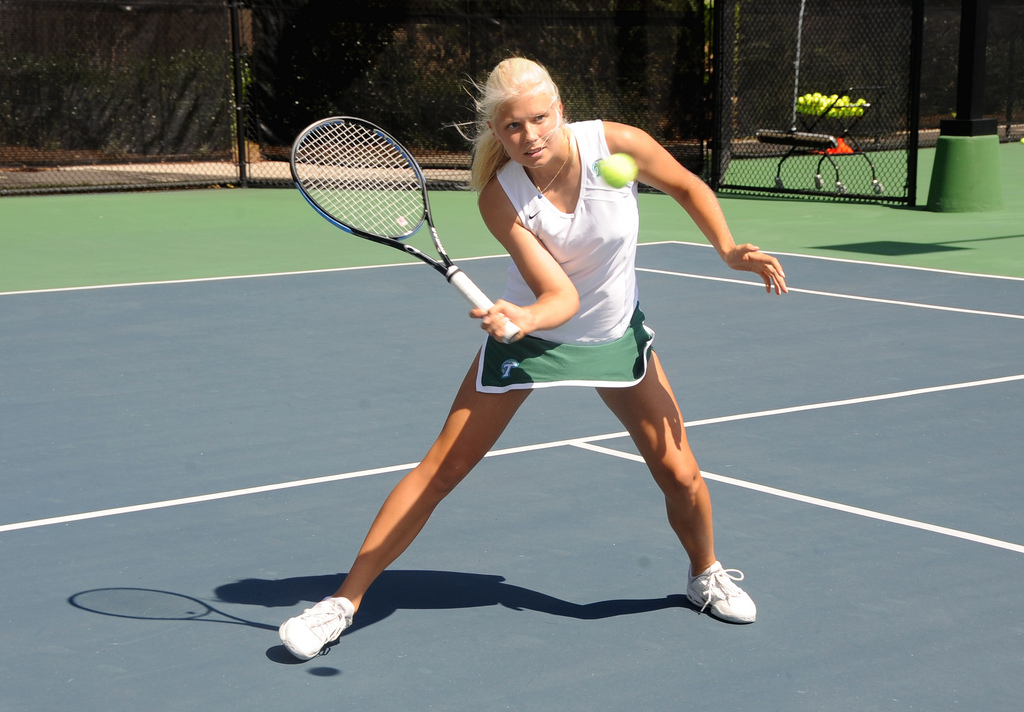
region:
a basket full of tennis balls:
[762, 45, 899, 204]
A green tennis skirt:
[378, 277, 742, 442]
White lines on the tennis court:
[762, 357, 986, 585]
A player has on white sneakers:
[236, 476, 795, 678]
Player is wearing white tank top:
[456, 88, 719, 366]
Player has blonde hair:
[450, 39, 631, 230]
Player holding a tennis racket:
[216, 88, 717, 380]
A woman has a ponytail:
[438, 47, 646, 255]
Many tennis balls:
[764, 37, 898, 202]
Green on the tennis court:
[48, 195, 186, 263]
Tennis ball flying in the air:
[574, 152, 655, 213]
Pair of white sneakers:
[256, 523, 819, 689]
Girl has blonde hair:
[427, 52, 625, 221]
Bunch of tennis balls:
[743, 44, 912, 248]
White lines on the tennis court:
[643, 262, 1021, 638]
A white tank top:
[438, 65, 681, 402]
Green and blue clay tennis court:
[66, 200, 881, 656]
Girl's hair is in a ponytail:
[403, 40, 613, 242]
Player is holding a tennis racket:
[257, 99, 705, 428]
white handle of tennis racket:
[461, 277, 494, 313]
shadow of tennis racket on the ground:
[62, 582, 234, 660]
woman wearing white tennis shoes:
[683, 558, 760, 626]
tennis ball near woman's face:
[520, 114, 658, 203]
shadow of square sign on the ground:
[806, 220, 1022, 263]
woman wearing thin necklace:
[524, 157, 573, 203]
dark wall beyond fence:
[9, 7, 231, 151]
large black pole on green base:
[934, 42, 999, 219]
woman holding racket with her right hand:
[477, 283, 542, 342]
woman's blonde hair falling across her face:
[533, 111, 573, 149]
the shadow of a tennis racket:
[53, 525, 269, 659]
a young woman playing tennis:
[204, 21, 811, 674]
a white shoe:
[672, 554, 770, 628]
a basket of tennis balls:
[742, 68, 907, 204]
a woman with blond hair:
[454, 49, 584, 204]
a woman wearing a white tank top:
[448, 55, 652, 344]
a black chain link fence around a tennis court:
[2, 19, 247, 198]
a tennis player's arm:
[435, 172, 587, 349]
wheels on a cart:
[758, 160, 902, 200]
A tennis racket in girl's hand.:
[269, 99, 525, 365]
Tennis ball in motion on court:
[591, 141, 643, 203]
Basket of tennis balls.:
[756, 59, 897, 200]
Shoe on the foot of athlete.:
[266, 580, 365, 675]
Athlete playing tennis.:
[271, 18, 800, 685]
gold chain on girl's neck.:
[509, 112, 590, 212]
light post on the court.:
[923, 0, 1012, 220]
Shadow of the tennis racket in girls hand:
[37, 558, 319, 657]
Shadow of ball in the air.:
[287, 638, 360, 690]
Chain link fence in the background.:
[7, 12, 236, 200]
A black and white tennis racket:
[275, 93, 532, 384]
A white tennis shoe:
[262, 577, 456, 696]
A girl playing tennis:
[158, 32, 946, 697]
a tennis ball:
[594, 140, 656, 198]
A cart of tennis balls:
[780, 71, 898, 201]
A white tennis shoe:
[653, 532, 808, 654]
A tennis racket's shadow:
[46, 515, 281, 677]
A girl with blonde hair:
[436, 42, 588, 224]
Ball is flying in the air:
[573, 150, 672, 231]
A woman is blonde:
[421, 43, 614, 261]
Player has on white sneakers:
[228, 503, 801, 692]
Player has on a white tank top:
[444, 74, 681, 395]